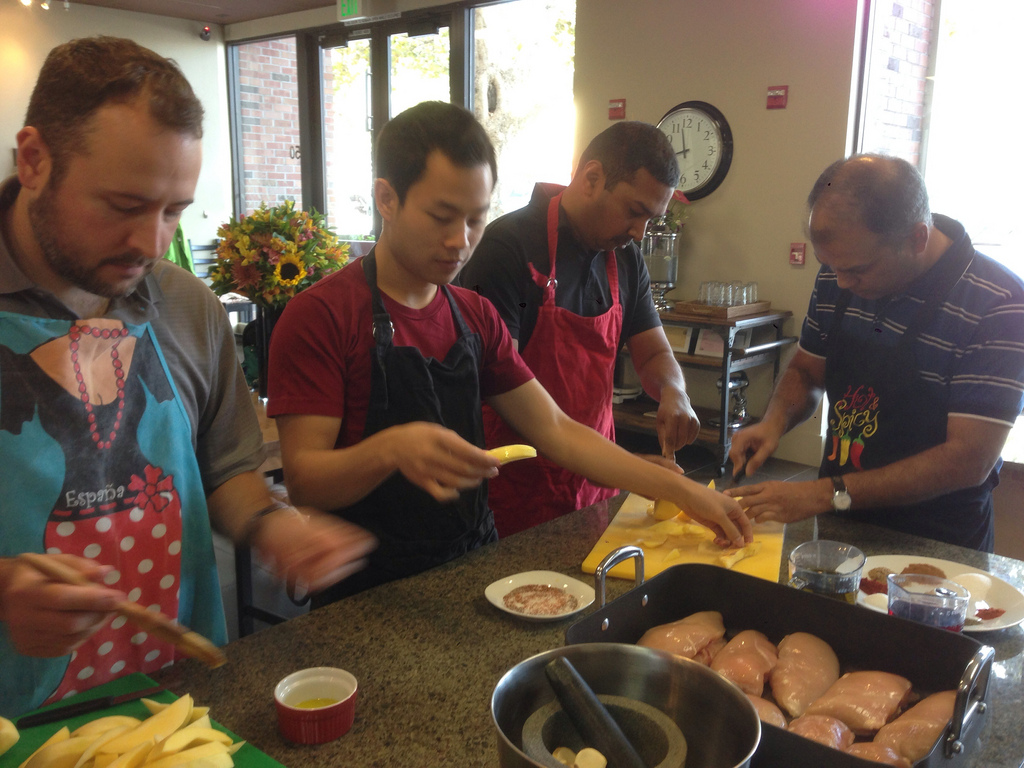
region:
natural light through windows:
[237, 3, 1019, 354]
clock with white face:
[655, 98, 732, 204]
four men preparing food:
[3, 34, 1022, 763]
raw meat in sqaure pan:
[566, 542, 988, 764]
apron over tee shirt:
[261, 253, 536, 602]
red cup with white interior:
[273, 663, 357, 744]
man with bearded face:
[11, 34, 205, 297]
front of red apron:
[487, 192, 624, 526]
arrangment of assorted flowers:
[209, 204, 342, 303]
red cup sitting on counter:
[253, 632, 405, 749]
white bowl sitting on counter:
[476, 546, 598, 626]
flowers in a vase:
[209, 195, 349, 320]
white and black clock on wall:
[643, 89, 735, 197]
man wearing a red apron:
[499, 104, 716, 364]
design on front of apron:
[812, 379, 898, 469]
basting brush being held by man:
[25, 540, 256, 680]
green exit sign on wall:
[323, 0, 387, 36]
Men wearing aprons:
[2, 28, 1021, 724]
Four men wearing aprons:
[0, 28, 1022, 712]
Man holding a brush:
[0, 31, 378, 728]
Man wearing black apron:
[261, 97, 758, 613]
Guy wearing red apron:
[447, 115, 708, 540]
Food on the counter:
[0, 467, 1022, 765]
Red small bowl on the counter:
[0, 461, 1016, 763]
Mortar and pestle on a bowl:
[485, 634, 771, 765]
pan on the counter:
[554, 529, 994, 767]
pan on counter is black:
[551, 532, 994, 767]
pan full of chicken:
[542, 529, 1018, 767]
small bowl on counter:
[263, 654, 368, 750]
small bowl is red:
[265, 659, 367, 748]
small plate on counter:
[471, 552, 601, 635]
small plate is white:
[477, 552, 598, 638]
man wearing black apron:
[327, 230, 521, 605]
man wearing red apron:
[474, 178, 640, 548]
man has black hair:
[356, 114, 519, 260]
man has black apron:
[383, 255, 505, 573]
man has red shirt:
[260, 278, 523, 570]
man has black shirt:
[418, 205, 693, 377]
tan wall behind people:
[585, 0, 839, 228]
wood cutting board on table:
[585, 480, 786, 597]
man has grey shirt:
[172, 281, 335, 512]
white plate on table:
[863, 524, 1012, 646]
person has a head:
[375, 104, 494, 279]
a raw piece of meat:
[715, 629, 774, 691]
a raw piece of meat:
[770, 629, 835, 715]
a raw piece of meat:
[800, 669, 912, 731]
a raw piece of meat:
[873, 686, 959, 762]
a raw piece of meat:
[788, 715, 852, 748]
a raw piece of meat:
[845, 739, 913, 766]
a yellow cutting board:
[585, 490, 785, 588]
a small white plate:
[487, 568, 595, 620]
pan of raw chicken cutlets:
[555, 538, 1004, 766]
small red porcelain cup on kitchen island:
[264, 658, 369, 751]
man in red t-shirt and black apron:
[262, 94, 759, 636]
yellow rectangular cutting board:
[574, 478, 791, 595]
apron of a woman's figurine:
[16, 302, 236, 686]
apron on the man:
[8, 269, 225, 690]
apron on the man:
[320, 248, 507, 587]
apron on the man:
[520, 194, 634, 527]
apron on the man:
[804, 220, 976, 559]